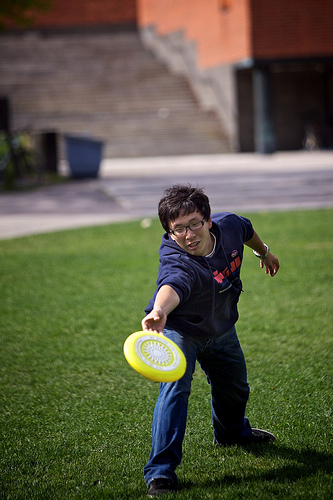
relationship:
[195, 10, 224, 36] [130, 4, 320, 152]
wall on side of building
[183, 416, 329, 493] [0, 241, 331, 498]
shadow on ground